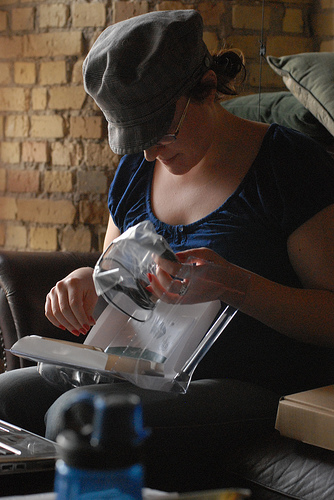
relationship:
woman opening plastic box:
[0, 8, 333, 473] [59, 246, 228, 397]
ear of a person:
[197, 72, 226, 109] [75, 23, 291, 322]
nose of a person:
[140, 139, 158, 160] [10, 14, 333, 426]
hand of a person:
[146, 229, 333, 332] [45, 26, 327, 363]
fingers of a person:
[23, 257, 131, 411] [44, 15, 288, 315]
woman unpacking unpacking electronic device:
[15, 8, 280, 454] [15, 216, 238, 399]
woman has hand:
[0, 8, 333, 473] [45, 265, 104, 337]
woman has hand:
[0, 8, 333, 473] [145, 245, 234, 303]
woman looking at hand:
[0, 8, 333, 473] [141, 245, 240, 310]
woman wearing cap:
[0, 8, 333, 473] [81, 9, 205, 150]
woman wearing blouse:
[55, 35, 326, 311] [104, 119, 326, 357]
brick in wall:
[56, 222, 97, 253] [0, 0, 332, 257]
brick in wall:
[26, 224, 62, 251] [0, 0, 332, 257]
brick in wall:
[1, 205, 31, 256] [0, 0, 332, 257]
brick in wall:
[3, 177, 77, 251] [0, 0, 332, 257]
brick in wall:
[14, 192, 77, 224] [13, 44, 54, 129]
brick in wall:
[0, 194, 20, 221] [2, 2, 94, 238]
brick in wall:
[4, 113, 66, 138] [0, 1, 146, 251]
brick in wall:
[15, 36, 58, 160] [6, 6, 83, 226]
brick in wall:
[18, 29, 84, 59] [0, 0, 332, 257]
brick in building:
[25, 215, 61, 254] [4, 5, 329, 249]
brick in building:
[12, 205, 70, 262] [4, 5, 329, 249]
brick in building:
[15, 192, 104, 226] [4, 5, 329, 249]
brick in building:
[0, 194, 17, 221] [0, 1, 330, 495]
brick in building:
[3, 159, 40, 196] [4, 5, 329, 249]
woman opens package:
[0, 8, 333, 473] [21, 263, 230, 386]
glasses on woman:
[148, 96, 189, 146] [0, 8, 333, 473]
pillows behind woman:
[218, 49, 333, 136] [0, 8, 333, 473]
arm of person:
[188, 214, 333, 334] [10, 14, 333, 426]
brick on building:
[77, 198, 108, 222] [4, 5, 329, 249]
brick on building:
[58, 223, 92, 251] [4, 5, 329, 249]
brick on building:
[264, 33, 315, 56] [4, 5, 329, 249]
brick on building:
[34, 58, 67, 83] [4, 5, 329, 249]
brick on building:
[19, 31, 84, 56] [4, 5, 329, 249]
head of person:
[79, 7, 249, 176] [81, 10, 222, 176]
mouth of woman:
[152, 149, 191, 170] [0, 8, 333, 473]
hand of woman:
[135, 236, 228, 313] [0, 8, 333, 473]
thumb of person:
[173, 244, 212, 266] [72, 22, 288, 290]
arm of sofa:
[142, 185, 325, 342] [0, 245, 332, 497]